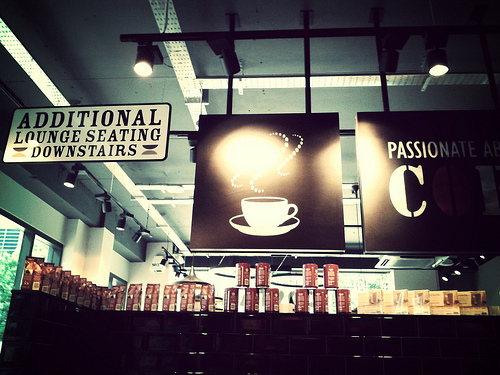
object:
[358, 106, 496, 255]
sign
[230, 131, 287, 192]
dots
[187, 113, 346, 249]
sign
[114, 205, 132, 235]
lights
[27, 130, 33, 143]
letter o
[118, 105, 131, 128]
letter n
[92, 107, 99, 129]
letter i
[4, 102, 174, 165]
sign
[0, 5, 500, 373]
restaurant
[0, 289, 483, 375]
ledge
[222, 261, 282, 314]
cans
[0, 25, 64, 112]
beams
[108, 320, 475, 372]
tile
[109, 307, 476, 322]
shelf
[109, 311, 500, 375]
drawers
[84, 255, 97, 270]
white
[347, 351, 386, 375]
silver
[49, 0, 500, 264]
ceiling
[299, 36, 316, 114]
hanging lights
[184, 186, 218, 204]
shining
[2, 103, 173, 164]
oblong sign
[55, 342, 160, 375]
seats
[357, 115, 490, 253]
dark sign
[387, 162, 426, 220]
word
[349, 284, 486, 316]
packages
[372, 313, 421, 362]
pattern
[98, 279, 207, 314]
packages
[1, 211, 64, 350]
window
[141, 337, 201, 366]
coffee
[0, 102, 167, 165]
informational sign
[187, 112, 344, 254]
poster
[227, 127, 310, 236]
coffee image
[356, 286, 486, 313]
boxes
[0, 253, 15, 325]
trees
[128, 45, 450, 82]
two lights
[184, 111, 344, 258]
image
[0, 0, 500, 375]
indoors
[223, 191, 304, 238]
coffee cup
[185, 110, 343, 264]
banner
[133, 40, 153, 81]
light fixture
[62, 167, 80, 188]
lights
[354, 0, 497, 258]
advertising board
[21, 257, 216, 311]
coffee bags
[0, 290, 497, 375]
counter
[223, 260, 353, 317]
boxes